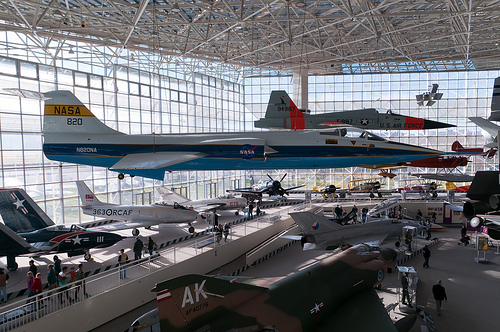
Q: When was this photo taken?
A: During the day.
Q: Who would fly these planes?
A: A pilot.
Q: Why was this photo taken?
A: To show the planes.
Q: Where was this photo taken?
A: Inside a building.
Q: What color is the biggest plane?
A: Blue and white.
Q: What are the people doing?
A: Looking at the planes.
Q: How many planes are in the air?
A: Three.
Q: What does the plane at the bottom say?
A: AK.